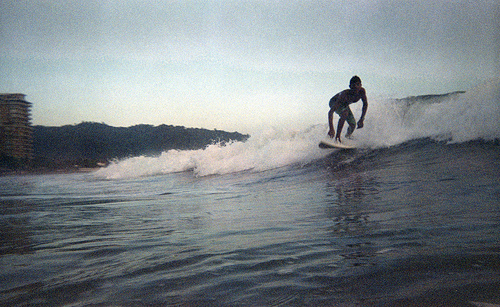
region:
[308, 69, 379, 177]
surfer riding a wave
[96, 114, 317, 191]
ocean wave as it's breaking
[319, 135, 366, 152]
surfboard in the water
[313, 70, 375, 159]
person surfing in the ocean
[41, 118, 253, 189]
coastline behind breaking wave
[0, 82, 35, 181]
multi story building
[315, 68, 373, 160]
young man on surfboard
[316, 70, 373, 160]
young man surfing in ocean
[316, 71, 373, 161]
young man riding white surfboard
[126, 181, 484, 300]
dark water with few ripples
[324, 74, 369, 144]
A male surfing in the ocean.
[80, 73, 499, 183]
A large ocean wave.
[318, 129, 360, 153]
A white colored surfboard.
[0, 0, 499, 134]
A background of sky.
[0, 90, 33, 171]
A large distant building.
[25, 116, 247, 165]
A large distant mountain.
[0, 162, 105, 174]
A strip of sandy beach.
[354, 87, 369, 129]
A male human arm.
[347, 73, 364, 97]
A male human head.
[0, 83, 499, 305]
A large area of water.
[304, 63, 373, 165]
woman riding a surfboard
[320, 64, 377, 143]
woman is crouched over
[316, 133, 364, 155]
surfboard is white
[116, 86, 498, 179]
woman riding on wave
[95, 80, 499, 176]
wave is white and foamy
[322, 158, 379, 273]
surfers shadow is cast in water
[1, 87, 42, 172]
large building to the left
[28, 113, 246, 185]
small hill in background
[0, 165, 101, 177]
shoreline in front of building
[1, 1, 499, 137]
sky is very overcast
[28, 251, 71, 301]
Small ripples in the water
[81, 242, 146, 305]
Small ripples in the water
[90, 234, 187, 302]
Small ripples in the water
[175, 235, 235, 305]
Small ripples in the water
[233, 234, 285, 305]
Small ripples in the water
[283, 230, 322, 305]
Small ripples in the water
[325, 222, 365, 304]
Small ripples in the water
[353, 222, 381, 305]
Small ripples in the water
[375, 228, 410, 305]
Small ripples in the water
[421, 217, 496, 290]
Small ripples in the water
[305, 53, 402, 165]
a man surfing in the ocean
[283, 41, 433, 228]
a man surfing in the water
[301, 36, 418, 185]
a man riding a surf board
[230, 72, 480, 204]
a man riding a surf board on a wave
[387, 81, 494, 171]
a white wave in the water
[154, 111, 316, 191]
a white wave in the ocean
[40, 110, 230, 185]
a mountain with trees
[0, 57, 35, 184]
a tall building next to the water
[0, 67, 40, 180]
a tall building with several levels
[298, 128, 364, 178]
a white surf board